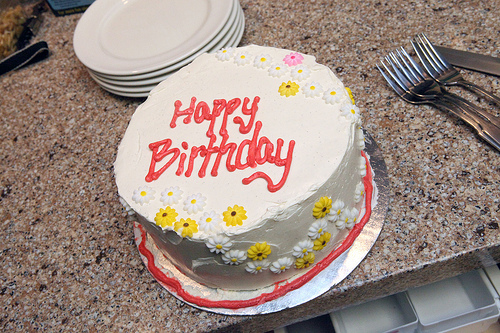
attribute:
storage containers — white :
[333, 262, 499, 332]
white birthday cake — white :
[113, 40, 377, 300]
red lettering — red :
[141, 91, 299, 194]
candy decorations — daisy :
[113, 44, 375, 321]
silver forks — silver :
[375, 29, 499, 156]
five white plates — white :
[70, 0, 259, 104]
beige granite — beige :
[0, 1, 500, 331]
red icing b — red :
[142, 139, 185, 183]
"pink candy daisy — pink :
[109, 40, 381, 286]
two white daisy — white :
[304, 80, 344, 108]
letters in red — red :
[145, 80, 297, 195]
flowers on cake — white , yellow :
[114, 26, 374, 300]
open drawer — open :
[327, 257, 498, 330]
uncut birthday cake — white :
[113, 48, 381, 306]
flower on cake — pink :
[274, 46, 308, 68]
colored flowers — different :
[120, 44, 378, 274]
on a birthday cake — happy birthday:
[141, 48, 306, 191]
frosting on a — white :
[115, 45, 380, 302]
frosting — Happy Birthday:
[130, 79, 291, 201]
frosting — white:
[305, 123, 338, 213]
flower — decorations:
[150, 189, 217, 240]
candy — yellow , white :
[117, 175, 246, 246]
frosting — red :
[117, 147, 377, 314]